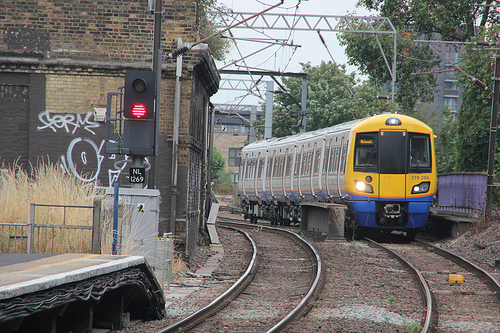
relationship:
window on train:
[318, 145, 335, 190] [215, 92, 458, 255]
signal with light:
[120, 69, 158, 157] [128, 100, 150, 119]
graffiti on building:
[38, 104, 112, 187] [45, 38, 238, 250]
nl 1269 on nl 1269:
[124, 161, 167, 194] [128, 167, 146, 183]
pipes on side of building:
[188, 180, 218, 254] [5, 12, 175, 256]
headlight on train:
[354, 181, 366, 192] [240, 112, 440, 243]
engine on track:
[274, 83, 444, 226] [209, 226, 498, 321]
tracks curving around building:
[162, 209, 497, 331] [12, 16, 212, 235]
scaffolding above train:
[202, 3, 416, 87] [259, 105, 469, 216]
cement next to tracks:
[165, 243, 231, 310] [162, 209, 497, 331]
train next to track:
[236, 114, 440, 241] [210, 237, 492, 330]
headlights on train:
[410, 181, 430, 193] [229, 114, 432, 241]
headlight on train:
[356, 182, 366, 192] [229, 114, 432, 241]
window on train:
[409, 130, 432, 175] [229, 114, 432, 241]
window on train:
[352, 127, 373, 172] [229, 114, 432, 241]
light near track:
[122, 88, 153, 124] [156, 207, 336, 330]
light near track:
[122, 88, 153, 124] [350, 212, 499, 331]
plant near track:
[1, 150, 125, 248] [185, 230, 497, 317]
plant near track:
[451, 33, 498, 173] [185, 230, 497, 317]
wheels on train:
[276, 205, 301, 229] [240, 112, 440, 243]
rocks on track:
[282, 246, 419, 330] [134, 211, 324, 331]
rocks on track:
[282, 246, 419, 330] [362, 230, 499, 332]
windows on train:
[282, 117, 377, 193] [206, 102, 451, 275]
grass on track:
[404, 314, 424, 331] [162, 182, 482, 318]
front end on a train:
[339, 107, 447, 244] [243, 112, 427, 232]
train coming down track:
[240, 112, 440, 243] [155, 215, 499, 332]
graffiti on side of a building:
[38, 104, 112, 187] [2, 0, 221, 277]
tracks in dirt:
[173, 203, 498, 331] [132, 195, 499, 331]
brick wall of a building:
[1, 1, 200, 265] [2, 0, 221, 277]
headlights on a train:
[341, 165, 449, 206] [196, 80, 443, 247]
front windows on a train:
[356, 131, 431, 173] [240, 112, 440, 243]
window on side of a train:
[352, 133, 376, 172] [240, 112, 440, 243]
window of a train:
[352, 133, 376, 172] [234, 126, 449, 218]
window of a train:
[303, 144, 343, 200] [236, 114, 440, 241]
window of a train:
[275, 152, 313, 177] [240, 112, 440, 243]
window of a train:
[268, 153, 290, 186] [234, 102, 447, 252]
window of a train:
[409, 131, 432, 172] [240, 112, 440, 243]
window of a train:
[242, 155, 258, 180] [240, 112, 440, 243]